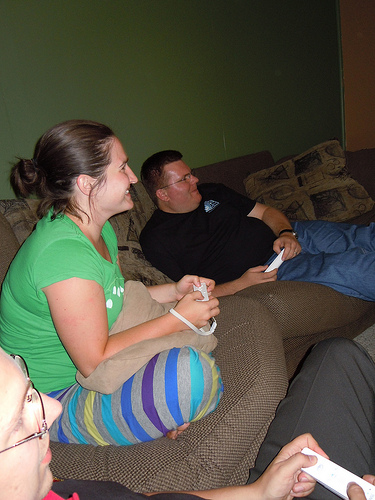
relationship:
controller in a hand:
[288, 439, 374, 496] [249, 417, 337, 488]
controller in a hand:
[288, 439, 374, 496] [343, 437, 374, 479]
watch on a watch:
[275, 228, 298, 236] [278, 227, 299, 237]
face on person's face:
[160, 157, 202, 211] [43, 128, 151, 221]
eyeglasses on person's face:
[161, 169, 196, 188] [43, 128, 151, 221]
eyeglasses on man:
[161, 169, 196, 188] [139, 146, 373, 325]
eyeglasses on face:
[161, 169, 196, 188] [160, 158, 200, 204]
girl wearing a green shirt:
[9, 120, 223, 443] [0, 205, 125, 395]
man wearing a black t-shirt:
[139, 145, 374, 326] [133, 179, 280, 295]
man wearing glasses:
[139, 146, 373, 325] [158, 168, 196, 192]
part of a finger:
[279, 443, 295, 456] [276, 434, 322, 450]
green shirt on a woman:
[4, 193, 134, 389] [16, 118, 208, 428]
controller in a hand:
[167, 278, 218, 337] [171, 290, 220, 331]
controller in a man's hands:
[256, 248, 299, 282] [240, 222, 303, 289]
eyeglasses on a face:
[170, 165, 211, 185] [160, 157, 202, 211]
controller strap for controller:
[169, 307, 220, 337] [189, 269, 228, 311]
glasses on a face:
[1, 346, 49, 458] [2, 349, 66, 499]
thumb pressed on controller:
[275, 452, 319, 476] [288, 439, 374, 496]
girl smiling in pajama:
[0, 120, 224, 446] [40, 346, 224, 447]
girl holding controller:
[0, 120, 224, 446] [193, 278, 210, 303]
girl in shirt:
[0, 120, 224, 446] [1, 206, 133, 399]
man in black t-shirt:
[139, 146, 373, 325] [139, 180, 276, 285]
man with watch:
[139, 146, 373, 325] [273, 225, 298, 235]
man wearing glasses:
[139, 146, 373, 325] [165, 165, 197, 192]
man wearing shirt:
[139, 146, 373, 325] [136, 186, 285, 283]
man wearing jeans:
[139, 146, 373, 325] [268, 207, 359, 311]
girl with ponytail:
[0, 120, 224, 446] [4, 153, 41, 200]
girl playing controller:
[0, 120, 224, 446] [256, 248, 299, 282]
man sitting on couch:
[139, 146, 373, 325] [0, 147, 360, 339]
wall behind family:
[4, 3, 342, 175] [4, 117, 374, 499]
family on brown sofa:
[4, 117, 374, 499] [0, 141, 375, 491]